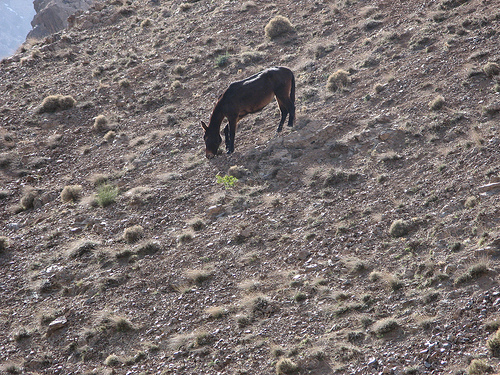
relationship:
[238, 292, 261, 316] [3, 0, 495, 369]
grass on dirt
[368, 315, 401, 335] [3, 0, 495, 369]
grass on dirt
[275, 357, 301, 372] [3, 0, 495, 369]
grass on dirt